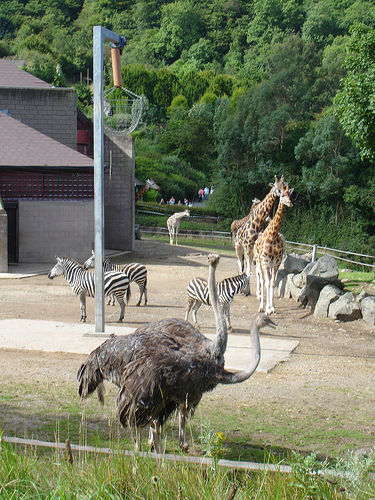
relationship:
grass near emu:
[1, 376, 374, 497] [73, 308, 287, 451]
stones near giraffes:
[274, 247, 374, 325] [230, 173, 301, 314]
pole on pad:
[93, 23, 130, 335] [0, 316, 302, 376]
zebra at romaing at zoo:
[184, 273, 252, 335] [40, 168, 302, 465]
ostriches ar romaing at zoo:
[76, 248, 282, 450] [8, 152, 374, 499]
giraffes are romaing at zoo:
[231, 171, 294, 314] [3, 229, 369, 496]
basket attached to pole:
[106, 36, 123, 89] [86, 20, 132, 340]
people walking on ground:
[139, 182, 226, 209] [1, 189, 371, 498]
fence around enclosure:
[137, 221, 374, 275] [1, 226, 363, 497]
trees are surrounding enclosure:
[1, 1, 372, 264] [6, 178, 366, 449]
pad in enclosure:
[1, 318, 298, 360] [1, 226, 363, 497]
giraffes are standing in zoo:
[230, 173, 301, 314] [0, 0, 375, 493]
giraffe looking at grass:
[166, 203, 191, 245] [141, 232, 372, 277]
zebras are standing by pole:
[44, 242, 149, 327] [89, 24, 123, 335]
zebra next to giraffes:
[182, 273, 258, 330] [231, 171, 294, 314]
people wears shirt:
[203, 185, 209, 200] [202, 187, 208, 193]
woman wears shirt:
[198, 184, 204, 198] [195, 189, 205, 198]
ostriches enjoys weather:
[66, 244, 284, 470] [3, 7, 371, 499]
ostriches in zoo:
[76, 311, 279, 455] [0, 24, 370, 493]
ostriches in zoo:
[66, 244, 284, 470] [6, 161, 372, 467]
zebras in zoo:
[47, 254, 132, 324] [3, 206, 373, 462]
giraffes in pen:
[233, 173, 288, 302] [3, 208, 373, 465]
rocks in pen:
[276, 243, 374, 322] [3, 208, 373, 465]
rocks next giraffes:
[307, 282, 347, 320] [253, 181, 294, 316]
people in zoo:
[193, 183, 217, 203] [0, 24, 370, 493]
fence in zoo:
[135, 224, 375, 276] [0, 24, 370, 493]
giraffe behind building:
[134, 174, 151, 203] [0, 57, 138, 274]